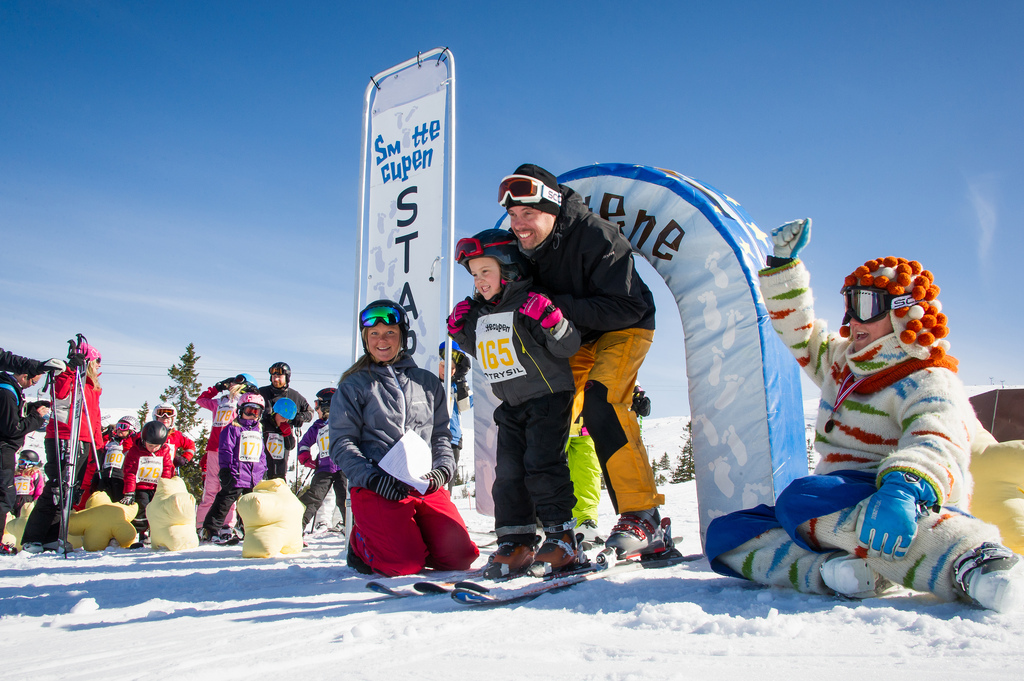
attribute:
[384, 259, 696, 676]
girl — skiing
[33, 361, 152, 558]
camera — black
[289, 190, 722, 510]
sign — white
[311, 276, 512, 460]
woman — seated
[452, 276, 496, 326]
girl — prepared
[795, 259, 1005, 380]
hat — strange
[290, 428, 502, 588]
pants — pink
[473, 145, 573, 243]
goggles — white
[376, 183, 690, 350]
goggles — red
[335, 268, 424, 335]
goggles — green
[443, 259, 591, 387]
sign — white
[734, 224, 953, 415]
goggles — black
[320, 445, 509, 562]
pants — red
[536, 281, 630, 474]
pants — yellow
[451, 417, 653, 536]
pants — black